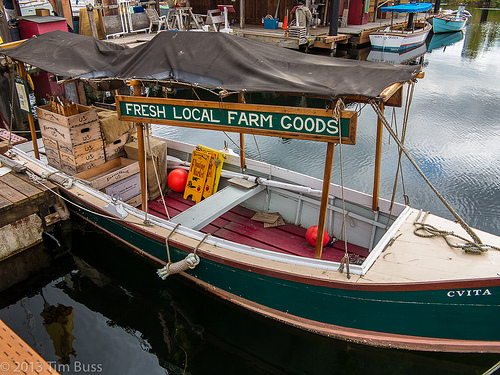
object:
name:
[447, 288, 492, 297]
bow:
[413, 222, 500, 254]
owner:
[1, 360, 100, 375]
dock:
[8, 183, 28, 200]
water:
[418, 109, 457, 131]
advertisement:
[115, 95, 358, 145]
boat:
[0, 29, 500, 353]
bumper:
[183, 144, 228, 204]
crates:
[35, 101, 105, 176]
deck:
[241, 226, 250, 230]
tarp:
[276, 74, 293, 83]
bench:
[167, 184, 267, 231]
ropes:
[84, 208, 146, 225]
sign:
[315, 118, 326, 133]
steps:
[44, 200, 70, 226]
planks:
[107, 172, 139, 193]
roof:
[179, 50, 200, 83]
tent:
[163, 35, 213, 48]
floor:
[275, 242, 304, 253]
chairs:
[35, 8, 50, 16]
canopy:
[0, 29, 423, 100]